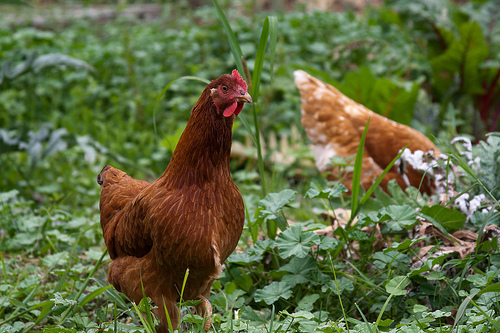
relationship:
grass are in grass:
[1, 8, 484, 331] [1, 8, 484, 331]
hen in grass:
[89, 58, 261, 329] [1, 8, 484, 331]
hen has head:
[89, 58, 261, 329] [208, 69, 252, 118]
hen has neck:
[89, 58, 261, 329] [177, 107, 239, 180]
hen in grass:
[282, 62, 467, 243] [1, 8, 484, 331]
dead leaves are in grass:
[296, 205, 497, 279] [1, 8, 484, 331]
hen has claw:
[89, 58, 261, 329] [196, 294, 222, 332]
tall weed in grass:
[211, 0, 285, 259] [1, 8, 484, 331]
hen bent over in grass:
[282, 62, 467, 243] [1, 8, 484, 331]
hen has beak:
[89, 58, 261, 329] [232, 89, 260, 113]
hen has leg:
[89, 58, 261, 329] [114, 245, 179, 330]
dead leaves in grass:
[296, 205, 497, 279] [1, 8, 484, 331]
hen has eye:
[89, 58, 261, 329] [216, 82, 234, 97]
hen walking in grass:
[89, 58, 261, 329] [1, 8, 484, 331]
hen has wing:
[282, 62, 467, 243] [280, 71, 393, 194]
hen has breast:
[89, 58, 261, 329] [137, 160, 254, 309]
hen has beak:
[89, 58, 261, 329] [239, 92, 253, 104]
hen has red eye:
[89, 58, 261, 329] [216, 82, 234, 97]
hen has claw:
[89, 58, 261, 329] [194, 295, 213, 332]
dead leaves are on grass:
[296, 205, 497, 279] [1, 8, 484, 331]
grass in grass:
[1, 8, 484, 331] [1, 8, 484, 331]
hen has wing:
[89, 58, 261, 329] [98, 177, 163, 275]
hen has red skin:
[89, 58, 261, 329] [217, 96, 271, 135]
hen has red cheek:
[89, 58, 261, 329] [209, 83, 230, 103]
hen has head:
[89, 58, 261, 329] [198, 67, 253, 134]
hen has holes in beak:
[89, 58, 261, 329] [237, 87, 246, 99]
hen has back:
[89, 58, 261, 329] [96, 162, 199, 220]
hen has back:
[89, 58, 261, 329] [96, 164, 138, 196]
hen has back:
[282, 62, 467, 243] [290, 68, 369, 137]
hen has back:
[282, 62, 467, 243] [343, 105, 426, 160]